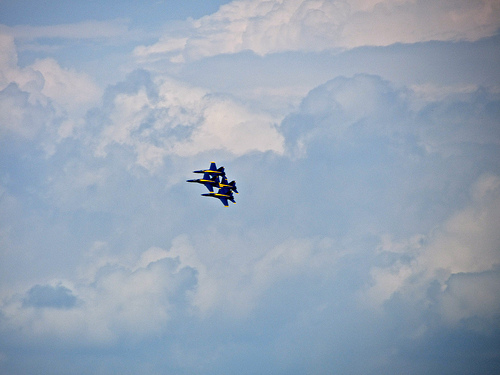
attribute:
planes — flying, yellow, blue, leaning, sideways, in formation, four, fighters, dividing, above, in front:
[174, 157, 247, 211]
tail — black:
[230, 177, 239, 194]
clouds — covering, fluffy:
[173, 6, 396, 116]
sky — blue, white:
[58, 4, 405, 156]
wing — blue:
[213, 195, 236, 210]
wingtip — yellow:
[222, 202, 230, 208]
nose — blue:
[180, 177, 192, 188]